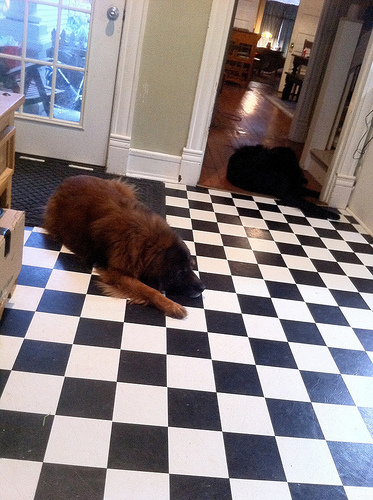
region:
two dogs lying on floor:
[43, 143, 326, 310]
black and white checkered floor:
[242, 279, 332, 377]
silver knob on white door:
[101, 3, 124, 33]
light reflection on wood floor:
[231, 88, 261, 137]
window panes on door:
[22, 8, 101, 127]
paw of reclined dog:
[110, 276, 187, 322]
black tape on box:
[0, 222, 26, 277]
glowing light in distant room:
[257, 27, 276, 44]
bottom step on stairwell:
[310, 142, 343, 171]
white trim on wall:
[192, 8, 230, 116]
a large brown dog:
[41, 167, 203, 322]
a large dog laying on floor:
[41, 172, 211, 318]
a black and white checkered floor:
[21, 172, 371, 498]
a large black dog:
[225, 139, 343, 220]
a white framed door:
[1, 1, 123, 169]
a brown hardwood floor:
[194, 80, 329, 203]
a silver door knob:
[105, 3, 118, 21]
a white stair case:
[309, 82, 371, 180]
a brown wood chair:
[223, 28, 261, 84]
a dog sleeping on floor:
[223, 139, 342, 221]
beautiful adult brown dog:
[38, 162, 228, 321]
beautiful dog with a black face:
[24, 152, 235, 336]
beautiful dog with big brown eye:
[30, 144, 203, 336]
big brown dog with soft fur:
[36, 164, 212, 347]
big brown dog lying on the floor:
[40, 154, 201, 350]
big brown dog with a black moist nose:
[72, 222, 231, 338]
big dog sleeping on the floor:
[44, 161, 228, 335]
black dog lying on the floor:
[216, 138, 328, 232]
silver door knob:
[67, 6, 126, 45]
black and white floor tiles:
[27, 318, 303, 465]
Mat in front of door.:
[0, 1, 177, 247]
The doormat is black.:
[13, 152, 179, 251]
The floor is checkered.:
[2, 149, 372, 498]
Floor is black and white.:
[4, 152, 372, 498]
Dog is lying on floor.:
[30, 164, 243, 369]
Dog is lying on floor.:
[217, 130, 347, 240]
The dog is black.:
[221, 133, 343, 230]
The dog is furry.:
[226, 118, 345, 233]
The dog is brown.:
[36, 160, 223, 332]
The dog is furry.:
[35, 155, 216, 329]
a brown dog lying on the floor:
[26, 171, 241, 364]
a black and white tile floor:
[154, 347, 312, 460]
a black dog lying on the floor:
[223, 120, 342, 249]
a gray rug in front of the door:
[0, 143, 173, 243]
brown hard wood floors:
[221, 87, 272, 141]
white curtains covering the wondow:
[256, 0, 303, 62]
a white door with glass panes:
[7, 0, 123, 173]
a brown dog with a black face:
[103, 212, 211, 341]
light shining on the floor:
[223, 71, 286, 142]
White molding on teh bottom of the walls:
[90, 131, 224, 197]